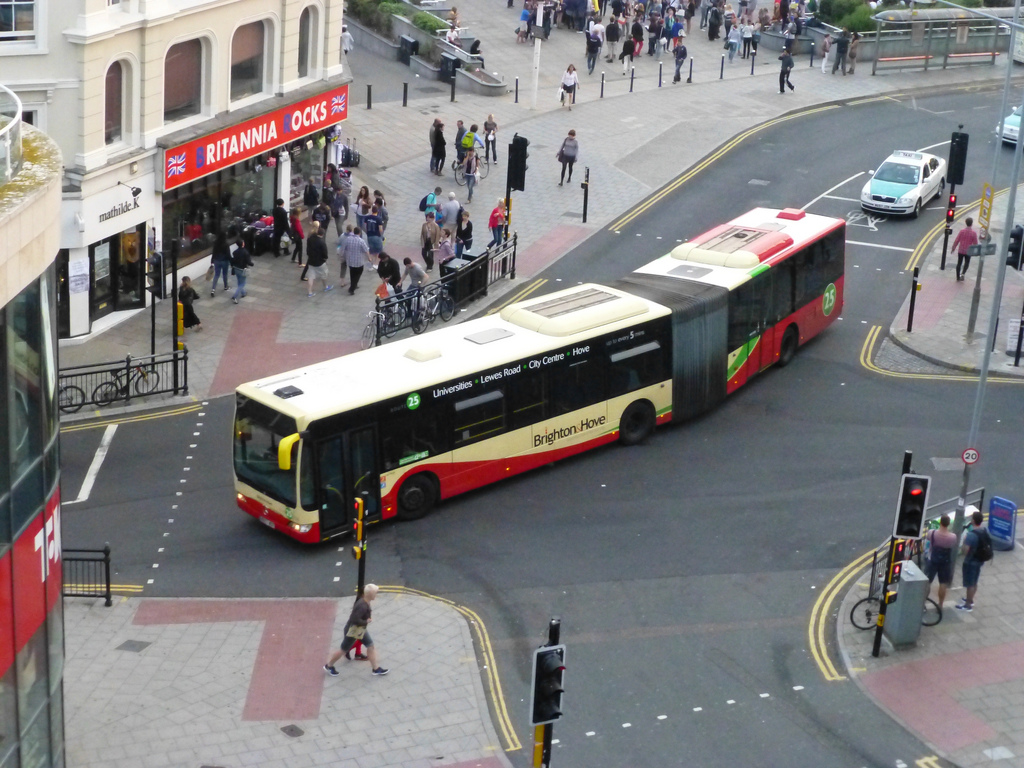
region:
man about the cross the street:
[314, 572, 419, 684]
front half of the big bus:
[220, 269, 705, 548]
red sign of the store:
[134, 75, 404, 200]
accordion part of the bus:
[611, 263, 751, 451]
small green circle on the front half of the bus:
[393, 392, 433, 415]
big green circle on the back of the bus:
[823, 278, 852, 321]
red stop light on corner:
[894, 464, 927, 547]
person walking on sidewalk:
[324, 582, 391, 680]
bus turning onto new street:
[231, 203, 845, 543]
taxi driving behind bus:
[859, 148, 946, 222]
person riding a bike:
[448, 124, 493, 185]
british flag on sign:
[160, 151, 192, 183]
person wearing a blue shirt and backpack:
[417, 184, 443, 219]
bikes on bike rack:
[53, 351, 194, 413]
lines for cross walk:
[145, 386, 210, 592]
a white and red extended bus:
[239, 199, 862, 538]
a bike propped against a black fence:
[84, 347, 174, 421]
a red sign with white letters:
[163, 81, 357, 187]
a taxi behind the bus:
[850, 148, 964, 219]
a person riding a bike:
[438, 127, 505, 198]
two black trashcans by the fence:
[439, 240, 498, 307]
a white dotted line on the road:
[133, 389, 207, 593]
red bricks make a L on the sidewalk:
[136, 584, 361, 722]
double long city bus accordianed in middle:
[234, 199, 865, 550]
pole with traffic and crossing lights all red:
[870, 444, 941, 701]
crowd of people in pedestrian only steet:
[539, 0, 833, 81]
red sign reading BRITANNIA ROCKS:
[171, 89, 378, 189]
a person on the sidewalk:
[541, 124, 608, 205]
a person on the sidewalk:
[315, 563, 440, 682]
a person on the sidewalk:
[947, 502, 987, 586]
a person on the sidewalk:
[269, 171, 304, 296]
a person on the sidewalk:
[313, 203, 394, 293]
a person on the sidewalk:
[342, 154, 397, 227]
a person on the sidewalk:
[541, 13, 611, 106]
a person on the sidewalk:
[743, 16, 769, 45]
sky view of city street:
[5, 4, 1021, 766]